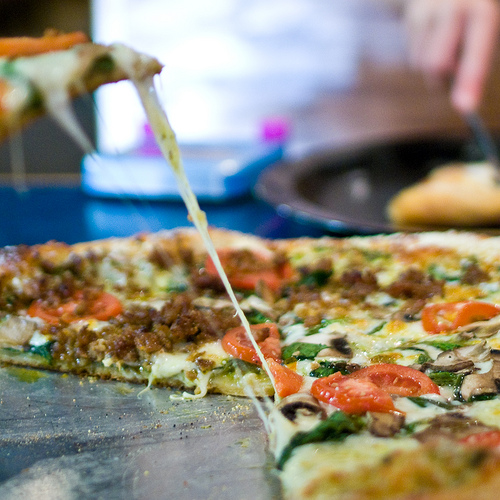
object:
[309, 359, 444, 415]
tomato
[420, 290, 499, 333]
tomato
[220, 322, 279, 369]
tomato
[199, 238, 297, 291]
tomato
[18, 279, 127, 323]
tomato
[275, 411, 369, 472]
vegetable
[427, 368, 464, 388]
vegetable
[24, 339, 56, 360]
vegetable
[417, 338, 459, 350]
vegetable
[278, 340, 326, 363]
vegetable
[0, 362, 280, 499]
metal plate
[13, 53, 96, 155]
cheese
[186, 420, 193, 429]
pizza crumb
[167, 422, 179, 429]
pizza crumb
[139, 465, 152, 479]
pizza crumb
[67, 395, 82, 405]
pizza crumb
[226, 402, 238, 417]
pizza crumb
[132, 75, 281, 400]
cheese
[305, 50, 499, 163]
ground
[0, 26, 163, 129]
pizza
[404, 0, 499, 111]
hand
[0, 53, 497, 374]
zander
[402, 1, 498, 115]
person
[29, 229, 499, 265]
crust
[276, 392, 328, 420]
mushroom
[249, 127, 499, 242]
plate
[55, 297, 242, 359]
sausage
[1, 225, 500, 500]
pizza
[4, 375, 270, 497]
empty space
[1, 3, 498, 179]
air